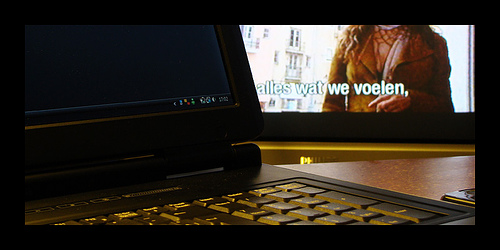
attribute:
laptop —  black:
[29, 29, 306, 229]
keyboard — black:
[48, 174, 443, 227]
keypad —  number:
[25, 165, 480, 225]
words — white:
[254, 75, 439, 103]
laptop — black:
[7, 11, 481, 243]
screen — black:
[9, 12, 224, 107]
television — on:
[241, 22, 473, 133]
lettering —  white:
[253, 78, 409, 99]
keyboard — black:
[51, 182, 451, 224]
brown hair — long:
[330, 25, 440, 58]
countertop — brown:
[260, 137, 497, 203]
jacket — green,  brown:
[321, 27, 452, 114]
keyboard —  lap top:
[188, 175, 373, 217]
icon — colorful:
[172, 100, 177, 105]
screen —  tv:
[239, 23, 476, 116]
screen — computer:
[5, 21, 268, 156]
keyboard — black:
[38, 172, 437, 229]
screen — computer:
[23, 25, 268, 174]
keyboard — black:
[32, 178, 478, 228]